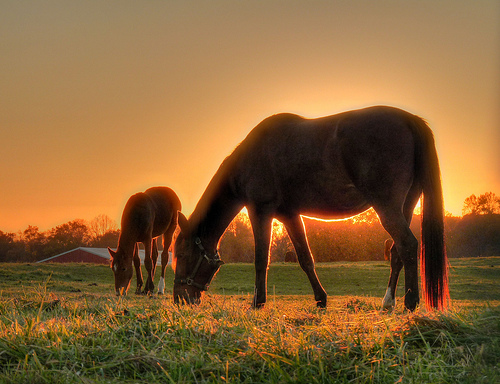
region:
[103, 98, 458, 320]
the horses are eating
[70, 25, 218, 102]
the sky is clear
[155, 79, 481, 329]
the horse is brown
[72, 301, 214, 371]
the grass is green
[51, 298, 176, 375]
the grass is long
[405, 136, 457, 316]
the tail is long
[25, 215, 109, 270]
the trees are far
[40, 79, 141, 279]
the sky is orange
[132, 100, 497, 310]
the horse is standing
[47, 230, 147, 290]
the roof is white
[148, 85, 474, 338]
Large brown horse eating grass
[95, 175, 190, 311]
Large brown horse eating grass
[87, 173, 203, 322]
Large brown horse with white foot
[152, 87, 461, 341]
Large brown horse with white foot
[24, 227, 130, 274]
Large red building with white roof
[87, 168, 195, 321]
Horse with head down eating grass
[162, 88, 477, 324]
Horse with head down eating grass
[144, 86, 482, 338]
Horse wearing a bridle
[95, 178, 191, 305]
Horse bent over eating grass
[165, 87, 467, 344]
Horse bent over eating grass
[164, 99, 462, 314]
horse eating grass in a field backlit by sunset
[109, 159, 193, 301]
second horse eating grass in field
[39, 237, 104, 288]
top of distant red building with white top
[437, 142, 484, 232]
bright yellow sunset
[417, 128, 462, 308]
tail of horse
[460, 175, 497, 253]
distant tree outlined by yellow sunset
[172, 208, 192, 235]
horses ear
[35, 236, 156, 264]
white roof of distant building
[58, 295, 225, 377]
green grass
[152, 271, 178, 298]
white spot on horses leg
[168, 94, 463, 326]
Horse eating green grass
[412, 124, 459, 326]
Tail of horse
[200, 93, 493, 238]
Sunset behind a horse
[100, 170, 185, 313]
Horse is eating grass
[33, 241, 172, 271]
Building behind the hill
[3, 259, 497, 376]
Grass in the prairie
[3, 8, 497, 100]
Sky is cloud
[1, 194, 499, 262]
Trees in the background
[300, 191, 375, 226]
Underbelly of horse is round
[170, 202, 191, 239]
Ear of horse is pointy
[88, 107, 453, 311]
two horses in a field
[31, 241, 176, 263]
red barn with white roof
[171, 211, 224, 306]
head of horse with bridle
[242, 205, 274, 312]
left front leg of horse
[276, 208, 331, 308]
right front leg of horse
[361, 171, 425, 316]
back legs of horse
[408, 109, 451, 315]
long tail of horse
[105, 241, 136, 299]
head of smaller horse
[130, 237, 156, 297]
front legs of smaller horse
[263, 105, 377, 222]
body of larger horse